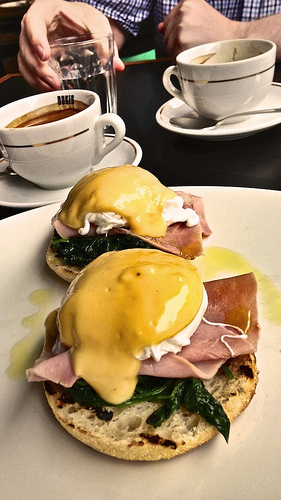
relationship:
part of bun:
[142, 431, 178, 456] [115, 356, 257, 459]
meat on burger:
[207, 273, 257, 372] [25, 161, 259, 467]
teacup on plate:
[160, 35, 278, 119] [153, 76, 279, 139]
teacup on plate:
[0, 85, 131, 196] [0, 128, 145, 209]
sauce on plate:
[191, 244, 279, 324] [0, 184, 279, 498]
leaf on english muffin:
[52, 233, 134, 252] [35, 230, 98, 282]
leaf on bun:
[142, 379, 240, 435] [43, 352, 259, 462]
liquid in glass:
[61, 72, 116, 116] [40, 33, 130, 128]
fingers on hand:
[16, 16, 66, 91] [2, 0, 125, 74]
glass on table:
[57, 39, 114, 82] [146, 129, 237, 175]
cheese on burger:
[62, 161, 171, 230] [34, 170, 256, 453]